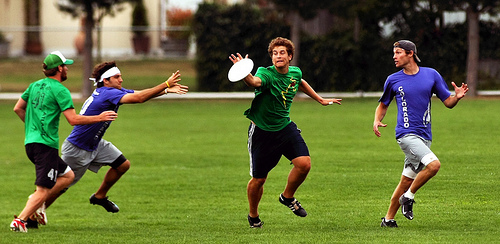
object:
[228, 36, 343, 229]
man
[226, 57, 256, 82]
frisbee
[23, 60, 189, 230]
man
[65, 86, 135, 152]
shirt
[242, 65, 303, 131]
shirt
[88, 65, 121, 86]
head band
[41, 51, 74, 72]
hat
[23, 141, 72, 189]
shorts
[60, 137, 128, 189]
shorts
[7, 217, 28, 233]
shoes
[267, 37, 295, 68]
head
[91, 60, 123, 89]
head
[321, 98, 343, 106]
hand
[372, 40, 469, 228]
man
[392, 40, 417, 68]
head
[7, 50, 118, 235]
man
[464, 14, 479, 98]
trunk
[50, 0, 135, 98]
tree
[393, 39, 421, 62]
hat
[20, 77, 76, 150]
shirt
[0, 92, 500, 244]
grass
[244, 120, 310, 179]
shorts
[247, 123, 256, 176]
stripes